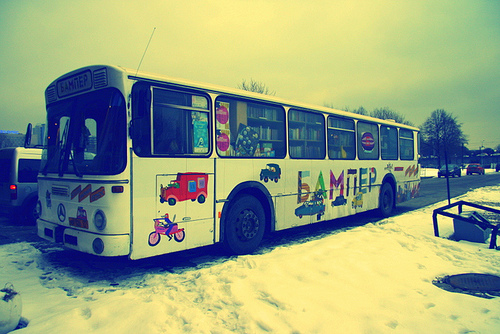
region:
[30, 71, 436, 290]
parked bus with writing on it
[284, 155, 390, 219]
writing on side of bus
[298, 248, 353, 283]
snow next to bus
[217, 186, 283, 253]
wheel of the bus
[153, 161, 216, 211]
red car on bus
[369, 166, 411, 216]
back tire of bus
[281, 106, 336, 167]
window on the bus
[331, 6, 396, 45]
sky above the ground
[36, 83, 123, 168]
front window of bus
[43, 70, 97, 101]
top of the bus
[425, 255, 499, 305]
Manhole cover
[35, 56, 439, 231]
Multi-colored bus with lots of images on it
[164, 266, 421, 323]
Ground is covered in snow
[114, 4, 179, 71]
Antenna sticking out from top of bus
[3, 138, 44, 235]
Vehicle right behind the bus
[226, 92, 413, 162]
Lots of books visible in bus windows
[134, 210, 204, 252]
Picture of a pink motorcycle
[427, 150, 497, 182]
Blue and red cars on the road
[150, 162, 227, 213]
Picture of a red truck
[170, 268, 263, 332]
Footprints in the snow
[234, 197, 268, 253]
The bus front tires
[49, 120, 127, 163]
the windshield of the bus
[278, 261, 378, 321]
white snow on the ground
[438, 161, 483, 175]
two cars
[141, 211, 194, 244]
drawing on the bus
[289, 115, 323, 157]
window on the bus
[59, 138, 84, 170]
the windshield wipers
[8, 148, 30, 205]
a van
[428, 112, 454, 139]
a tree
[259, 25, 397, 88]
a cloudy sky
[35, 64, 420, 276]
a white public service bus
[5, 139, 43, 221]
a white van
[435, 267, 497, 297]
a round man hole cover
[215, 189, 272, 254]
a front left bus tire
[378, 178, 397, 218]
a rear left bus tire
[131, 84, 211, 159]
a large bus window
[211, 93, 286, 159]
a large bus window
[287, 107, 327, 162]
a large bus window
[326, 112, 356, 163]
a large bus window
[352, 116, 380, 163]
a large bus window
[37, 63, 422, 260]
a mobile white library bus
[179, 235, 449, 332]
snow piled up on the side of the road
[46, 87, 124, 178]
the front windshield of the bus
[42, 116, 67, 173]
the front windshield wipers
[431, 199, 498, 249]
a metal frame around a meter box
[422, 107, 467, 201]
a tree on the street curb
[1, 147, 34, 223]
a silver mini van in the opposite direction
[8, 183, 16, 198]
the minivans red brake light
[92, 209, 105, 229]
the buses round headlight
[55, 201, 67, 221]
the Mercedes Benz logo on the front of the bus